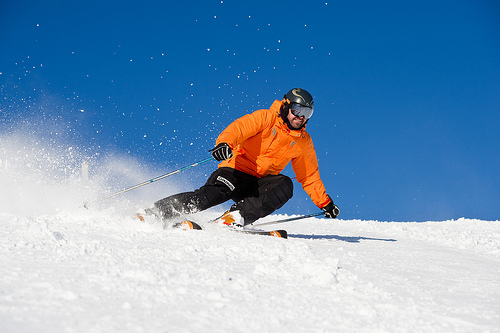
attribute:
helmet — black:
[284, 88, 315, 109]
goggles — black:
[281, 95, 314, 120]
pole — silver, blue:
[83, 154, 220, 212]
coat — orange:
[215, 100, 333, 211]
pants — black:
[153, 167, 293, 225]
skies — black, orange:
[129, 214, 288, 239]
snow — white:
[4, 210, 496, 328]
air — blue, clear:
[4, 9, 493, 215]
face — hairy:
[286, 109, 311, 129]